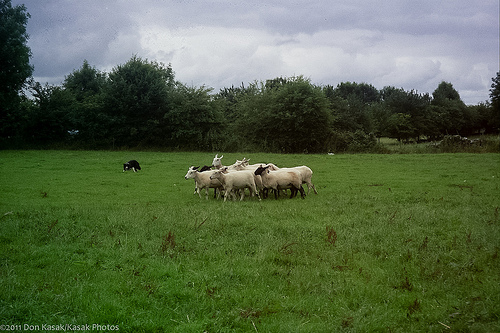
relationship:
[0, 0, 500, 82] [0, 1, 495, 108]
cloud in sky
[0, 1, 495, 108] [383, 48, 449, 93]
sky has cloud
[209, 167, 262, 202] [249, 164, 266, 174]
goat has face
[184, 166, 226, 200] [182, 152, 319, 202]
goat are in flock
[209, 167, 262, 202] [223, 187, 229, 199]
goat on leg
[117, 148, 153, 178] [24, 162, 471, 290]
animal on grass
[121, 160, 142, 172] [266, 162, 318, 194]
animal herding goat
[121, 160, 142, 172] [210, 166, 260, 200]
animal herding sheep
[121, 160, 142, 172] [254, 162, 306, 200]
animal herding goat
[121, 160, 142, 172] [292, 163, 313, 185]
animal herding sheep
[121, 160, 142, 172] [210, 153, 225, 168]
animal herding sheep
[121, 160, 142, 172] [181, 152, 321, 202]
animal herding flock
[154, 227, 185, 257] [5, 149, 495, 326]
brown bushes on grass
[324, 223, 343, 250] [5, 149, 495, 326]
brown bushes on grass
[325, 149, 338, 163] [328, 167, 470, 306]
white stack on grass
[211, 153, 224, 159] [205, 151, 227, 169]
horns on animal's head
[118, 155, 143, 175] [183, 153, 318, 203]
animal near pack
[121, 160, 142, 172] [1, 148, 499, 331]
animal grazing in field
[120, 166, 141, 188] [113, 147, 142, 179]
feet on animal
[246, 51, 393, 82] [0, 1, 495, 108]
cloud in sky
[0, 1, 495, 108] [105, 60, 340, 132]
sky above trees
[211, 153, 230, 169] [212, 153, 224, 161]
goat has ears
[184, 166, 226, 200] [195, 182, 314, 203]
goat have legs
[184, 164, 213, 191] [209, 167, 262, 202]
goat next to goat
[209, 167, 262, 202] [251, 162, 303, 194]
goat next to goat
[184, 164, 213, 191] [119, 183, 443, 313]
goat in field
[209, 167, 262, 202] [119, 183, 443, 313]
goat in field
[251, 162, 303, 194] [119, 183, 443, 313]
goat in field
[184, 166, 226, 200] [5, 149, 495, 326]
goat on grass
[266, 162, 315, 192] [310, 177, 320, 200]
goat has leg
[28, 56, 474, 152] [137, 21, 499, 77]
trees with clouds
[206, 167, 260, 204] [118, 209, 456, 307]
goat in field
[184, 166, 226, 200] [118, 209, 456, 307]
goat in field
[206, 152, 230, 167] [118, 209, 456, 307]
goat in field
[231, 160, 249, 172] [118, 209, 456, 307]
goat in field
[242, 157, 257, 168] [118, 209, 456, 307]
goat in field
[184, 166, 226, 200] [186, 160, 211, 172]
goat has head horns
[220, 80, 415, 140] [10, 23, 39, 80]
tree has leaves